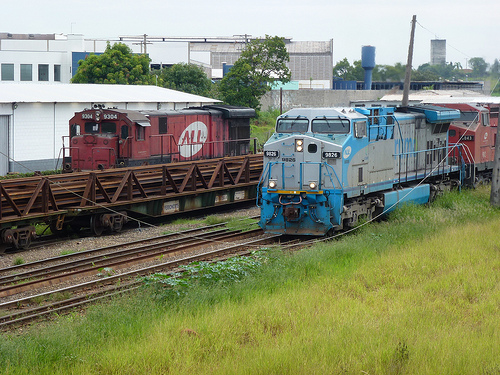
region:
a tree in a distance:
[213, 34, 285, 116]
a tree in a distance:
[176, 62, 205, 89]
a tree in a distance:
[144, 51, 167, 87]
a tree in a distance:
[121, 43, 151, 83]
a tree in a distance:
[82, 53, 117, 83]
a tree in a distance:
[336, 56, 358, 83]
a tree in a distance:
[358, 59, 374, 80]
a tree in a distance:
[373, 57, 391, 77]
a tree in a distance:
[464, 49, 487, 80]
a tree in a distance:
[411, 53, 438, 85]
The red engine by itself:
[55, 100, 255, 179]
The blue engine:
[249, 94, 459, 239]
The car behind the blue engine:
[430, 93, 499, 190]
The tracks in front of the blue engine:
[0, 233, 314, 330]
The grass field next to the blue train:
[0, 187, 497, 374]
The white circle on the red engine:
[177, 121, 212, 159]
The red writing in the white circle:
[183, 128, 205, 146]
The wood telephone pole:
[397, 11, 425, 113]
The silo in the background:
[426, 36, 452, 73]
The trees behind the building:
[69, 29, 291, 116]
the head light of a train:
[306, 176, 320, 192]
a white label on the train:
[173, 119, 213, 164]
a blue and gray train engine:
[250, 93, 470, 245]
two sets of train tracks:
[0, 208, 288, 333]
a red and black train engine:
[54, 99, 265, 206]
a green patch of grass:
[1, 176, 498, 373]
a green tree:
[69, 39, 163, 89]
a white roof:
[0, 76, 228, 122]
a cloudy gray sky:
[1, 0, 498, 71]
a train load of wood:
[1, 147, 276, 233]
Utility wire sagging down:
[2, 143, 494, 248]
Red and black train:
[61, 104, 258, 167]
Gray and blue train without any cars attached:
[259, 100, 479, 235]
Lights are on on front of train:
[267, 138, 319, 195]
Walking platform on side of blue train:
[396, 162, 461, 182]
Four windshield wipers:
[279, 107, 349, 127]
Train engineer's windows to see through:
[274, 117, 349, 134]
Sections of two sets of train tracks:
[3, 233, 305, 323]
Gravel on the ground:
[13, 221, 167, 255]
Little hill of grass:
[160, 227, 499, 372]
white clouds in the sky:
[116, 3, 293, 18]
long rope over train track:
[95, 203, 436, 270]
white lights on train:
[239, 168, 296, 207]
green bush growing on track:
[91, 260, 134, 283]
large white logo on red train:
[162, 106, 220, 174]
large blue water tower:
[350, 38, 397, 103]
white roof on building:
[15, 42, 179, 103]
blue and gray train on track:
[249, 84, 483, 244]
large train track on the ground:
[25, 238, 352, 338]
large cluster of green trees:
[95, 23, 355, 151]